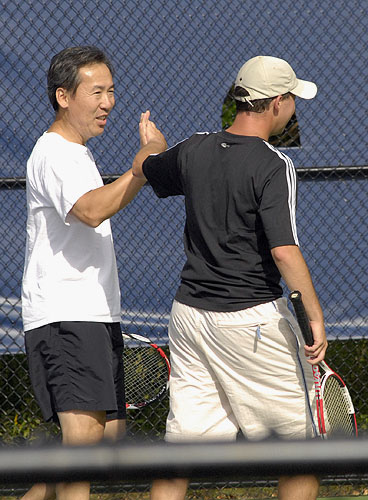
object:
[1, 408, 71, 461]
grass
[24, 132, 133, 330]
shirt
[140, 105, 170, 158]
hands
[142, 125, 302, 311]
shirt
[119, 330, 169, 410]
racket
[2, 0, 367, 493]
fence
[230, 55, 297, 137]
head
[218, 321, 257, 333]
pocket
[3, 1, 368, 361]
wall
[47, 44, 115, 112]
hair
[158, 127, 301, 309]
black shirt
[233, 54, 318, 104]
hat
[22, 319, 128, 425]
shorts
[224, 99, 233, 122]
blue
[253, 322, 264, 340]
zipper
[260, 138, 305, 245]
stripes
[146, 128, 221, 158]
stripes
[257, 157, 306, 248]
sleeve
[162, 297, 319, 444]
shorts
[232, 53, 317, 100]
cap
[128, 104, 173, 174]
high fiving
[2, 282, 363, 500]
court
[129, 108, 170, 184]
touching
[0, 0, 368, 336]
screen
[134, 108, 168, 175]
palms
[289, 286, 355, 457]
racket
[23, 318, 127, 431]
waist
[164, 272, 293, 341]
waist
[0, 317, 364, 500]
plants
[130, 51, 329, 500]
man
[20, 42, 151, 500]
man